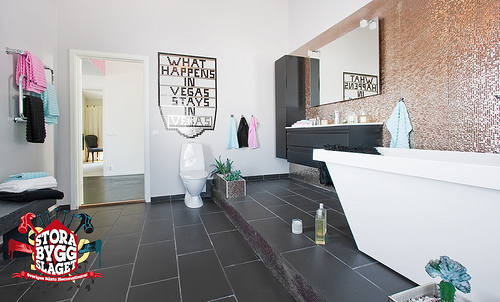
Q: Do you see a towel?
A: Yes, there is a towel.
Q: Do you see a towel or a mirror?
A: Yes, there is a towel.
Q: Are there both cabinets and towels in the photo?
A: Yes, there are both a towel and a cabinet.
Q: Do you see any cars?
A: No, there are no cars.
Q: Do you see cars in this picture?
A: No, there are no cars.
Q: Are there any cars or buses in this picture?
A: No, there are no cars or buses.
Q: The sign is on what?
A: The sign is on the wall.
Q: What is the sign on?
A: The sign is on the wall.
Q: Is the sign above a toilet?
A: Yes, the sign is above a toilet.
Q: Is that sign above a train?
A: No, the sign is above a toilet.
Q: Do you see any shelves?
A: No, there are no shelves.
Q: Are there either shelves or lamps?
A: No, there are no shelves or lamps.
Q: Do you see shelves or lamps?
A: No, there are no shelves or lamps.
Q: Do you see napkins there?
A: No, there are no napkins.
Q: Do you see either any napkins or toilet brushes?
A: No, there are no napkins or toilet brushes.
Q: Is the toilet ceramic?
A: Yes, the toilet is ceramic.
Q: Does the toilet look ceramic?
A: Yes, the toilet is ceramic.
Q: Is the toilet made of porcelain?
A: Yes, the toilet is made of porcelain.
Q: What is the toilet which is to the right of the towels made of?
A: The toilet is made of porcelain.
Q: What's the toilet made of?
A: The toilet is made of porcelain.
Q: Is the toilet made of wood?
A: No, the toilet is made of porcelain.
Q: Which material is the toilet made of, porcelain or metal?
A: The toilet is made of porcelain.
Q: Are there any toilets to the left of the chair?
A: No, the toilet is to the right of the chair.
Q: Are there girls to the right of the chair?
A: No, there is a toilet to the right of the chair.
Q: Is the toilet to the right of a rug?
A: No, the toilet is to the right of the chair.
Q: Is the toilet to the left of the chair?
A: No, the toilet is to the right of the chair.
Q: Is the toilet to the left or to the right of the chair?
A: The toilet is to the right of the chair.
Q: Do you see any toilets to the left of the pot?
A: Yes, there is a toilet to the left of the pot.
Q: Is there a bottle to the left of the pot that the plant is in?
A: No, there is a toilet to the left of the pot.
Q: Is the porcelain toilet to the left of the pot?
A: Yes, the toilet is to the left of the pot.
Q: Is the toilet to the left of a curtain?
A: No, the toilet is to the left of the pot.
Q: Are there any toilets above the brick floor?
A: Yes, there is a toilet above the floor.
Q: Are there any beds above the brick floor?
A: No, there is a toilet above the floor.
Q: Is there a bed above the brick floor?
A: No, there is a toilet above the floor.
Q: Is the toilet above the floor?
A: Yes, the toilet is above the floor.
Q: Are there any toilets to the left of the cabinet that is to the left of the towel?
A: Yes, there is a toilet to the left of the cabinet.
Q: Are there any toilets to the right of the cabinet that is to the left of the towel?
A: No, the toilet is to the left of the cabinet.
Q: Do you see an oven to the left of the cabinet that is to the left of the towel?
A: No, there is a toilet to the left of the cabinet.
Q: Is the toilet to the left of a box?
A: No, the toilet is to the left of a cabinet.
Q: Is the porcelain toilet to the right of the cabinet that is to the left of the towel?
A: No, the toilet is to the left of the cabinet.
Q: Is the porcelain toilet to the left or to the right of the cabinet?
A: The toilet is to the left of the cabinet.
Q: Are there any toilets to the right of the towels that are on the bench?
A: Yes, there is a toilet to the right of the towels.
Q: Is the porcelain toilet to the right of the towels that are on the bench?
A: Yes, the toilet is to the right of the towels.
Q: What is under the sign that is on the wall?
A: The toilet is under the sign.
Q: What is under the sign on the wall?
A: The toilet is under the sign.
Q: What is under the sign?
A: The toilet is under the sign.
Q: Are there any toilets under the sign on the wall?
A: Yes, there is a toilet under the sign.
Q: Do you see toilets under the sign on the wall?
A: Yes, there is a toilet under the sign.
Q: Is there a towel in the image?
A: Yes, there is a towel.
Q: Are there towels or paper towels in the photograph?
A: Yes, there is a towel.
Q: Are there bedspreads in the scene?
A: No, there are no bedspreads.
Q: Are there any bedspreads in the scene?
A: No, there are no bedspreads.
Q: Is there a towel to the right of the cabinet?
A: Yes, there is a towel to the right of the cabinet.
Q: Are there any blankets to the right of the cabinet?
A: No, there is a towel to the right of the cabinet.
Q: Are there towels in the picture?
A: Yes, there is a towel.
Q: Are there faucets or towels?
A: Yes, there is a towel.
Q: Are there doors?
A: Yes, there is a door.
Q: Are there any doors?
A: Yes, there is a door.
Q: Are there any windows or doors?
A: Yes, there is a door.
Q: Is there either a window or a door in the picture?
A: Yes, there is a door.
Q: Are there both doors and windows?
A: No, there is a door but no windows.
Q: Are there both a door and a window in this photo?
A: No, there is a door but no windows.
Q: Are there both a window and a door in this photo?
A: No, there is a door but no windows.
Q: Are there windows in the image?
A: No, there are no windows.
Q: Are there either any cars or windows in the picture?
A: No, there are no windows or cars.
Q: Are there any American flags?
A: No, there are no American flags.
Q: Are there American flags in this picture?
A: No, there are no American flags.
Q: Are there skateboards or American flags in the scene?
A: No, there are no American flags or skateboards.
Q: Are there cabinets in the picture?
A: Yes, there is a cabinet.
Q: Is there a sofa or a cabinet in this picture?
A: Yes, there is a cabinet.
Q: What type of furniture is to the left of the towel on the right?
A: The piece of furniture is a cabinet.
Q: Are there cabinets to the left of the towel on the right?
A: Yes, there is a cabinet to the left of the towel.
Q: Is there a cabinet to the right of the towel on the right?
A: No, the cabinet is to the left of the towel.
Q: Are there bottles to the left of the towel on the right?
A: No, there is a cabinet to the left of the towel.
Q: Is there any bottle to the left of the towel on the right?
A: No, there is a cabinet to the left of the towel.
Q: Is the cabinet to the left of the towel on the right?
A: Yes, the cabinet is to the left of the towel.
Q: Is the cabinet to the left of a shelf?
A: No, the cabinet is to the left of the towel.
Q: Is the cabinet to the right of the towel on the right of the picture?
A: No, the cabinet is to the left of the towel.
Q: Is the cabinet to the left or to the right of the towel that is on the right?
A: The cabinet is to the left of the towel.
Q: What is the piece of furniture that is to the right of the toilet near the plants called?
A: The piece of furniture is a cabinet.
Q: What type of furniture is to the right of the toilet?
A: The piece of furniture is a cabinet.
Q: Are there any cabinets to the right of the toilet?
A: Yes, there is a cabinet to the right of the toilet.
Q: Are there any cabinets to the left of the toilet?
A: No, the cabinet is to the right of the toilet.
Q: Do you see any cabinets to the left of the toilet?
A: No, the cabinet is to the right of the toilet.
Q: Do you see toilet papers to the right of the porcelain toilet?
A: No, there is a cabinet to the right of the toilet.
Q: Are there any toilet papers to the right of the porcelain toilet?
A: No, there is a cabinet to the right of the toilet.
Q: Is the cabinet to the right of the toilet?
A: Yes, the cabinet is to the right of the toilet.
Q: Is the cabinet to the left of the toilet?
A: No, the cabinet is to the right of the toilet.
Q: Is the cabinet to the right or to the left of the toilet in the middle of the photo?
A: The cabinet is to the right of the toilet.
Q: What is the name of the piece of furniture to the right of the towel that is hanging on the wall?
A: The piece of furniture is a cabinet.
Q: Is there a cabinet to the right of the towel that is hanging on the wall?
A: Yes, there is a cabinet to the right of the towel.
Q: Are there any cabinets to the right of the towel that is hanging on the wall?
A: Yes, there is a cabinet to the right of the towel.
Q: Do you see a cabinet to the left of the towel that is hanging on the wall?
A: No, the cabinet is to the right of the towel.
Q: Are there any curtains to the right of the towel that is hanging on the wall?
A: No, there is a cabinet to the right of the towel.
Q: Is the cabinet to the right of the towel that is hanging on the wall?
A: Yes, the cabinet is to the right of the towel.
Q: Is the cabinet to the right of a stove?
A: No, the cabinet is to the right of the towel.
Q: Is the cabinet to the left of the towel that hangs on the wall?
A: No, the cabinet is to the right of the towel.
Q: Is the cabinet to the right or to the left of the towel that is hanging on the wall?
A: The cabinet is to the right of the towel.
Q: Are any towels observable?
A: Yes, there is a towel.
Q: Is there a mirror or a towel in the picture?
A: Yes, there is a towel.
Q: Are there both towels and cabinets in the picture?
A: Yes, there are both a towel and a cabinet.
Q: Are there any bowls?
A: No, there are no bowls.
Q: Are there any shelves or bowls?
A: No, there are no bowls or shelves.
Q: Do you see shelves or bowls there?
A: No, there are no bowls or shelves.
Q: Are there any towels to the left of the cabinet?
A: Yes, there is a towel to the left of the cabinet.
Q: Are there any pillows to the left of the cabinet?
A: No, there is a towel to the left of the cabinet.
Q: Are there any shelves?
A: No, there are no shelves.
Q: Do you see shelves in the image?
A: No, there are no shelves.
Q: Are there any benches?
A: Yes, there is a bench.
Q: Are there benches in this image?
A: Yes, there is a bench.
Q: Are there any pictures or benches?
A: Yes, there is a bench.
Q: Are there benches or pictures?
A: Yes, there is a bench.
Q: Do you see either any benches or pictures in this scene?
A: Yes, there is a bench.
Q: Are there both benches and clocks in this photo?
A: No, there is a bench but no clocks.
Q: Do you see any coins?
A: No, there are no coins.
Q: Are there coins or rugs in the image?
A: No, there are no coins or rugs.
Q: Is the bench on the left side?
A: Yes, the bench is on the left of the image.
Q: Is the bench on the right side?
A: No, the bench is on the left of the image.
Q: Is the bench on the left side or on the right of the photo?
A: The bench is on the left of the image.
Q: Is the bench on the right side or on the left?
A: The bench is on the left of the image.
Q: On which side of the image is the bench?
A: The bench is on the left of the image.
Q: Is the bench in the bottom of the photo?
A: Yes, the bench is in the bottom of the image.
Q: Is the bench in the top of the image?
A: No, the bench is in the bottom of the image.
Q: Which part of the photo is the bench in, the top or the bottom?
A: The bench is in the bottom of the image.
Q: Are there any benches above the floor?
A: Yes, there is a bench above the floor.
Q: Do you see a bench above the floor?
A: Yes, there is a bench above the floor.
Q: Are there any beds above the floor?
A: No, there is a bench above the floor.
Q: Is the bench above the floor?
A: Yes, the bench is above the floor.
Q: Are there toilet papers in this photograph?
A: No, there are no toilet papers.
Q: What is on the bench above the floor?
A: The towels are on the bench.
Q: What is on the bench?
A: The towels are on the bench.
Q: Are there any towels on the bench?
A: Yes, there are towels on the bench.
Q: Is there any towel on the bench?
A: Yes, there are towels on the bench.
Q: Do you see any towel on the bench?
A: Yes, there are towels on the bench.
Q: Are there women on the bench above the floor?
A: No, there are towels on the bench.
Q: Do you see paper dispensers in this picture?
A: No, there are no paper dispensers.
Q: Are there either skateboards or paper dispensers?
A: No, there are no paper dispensers or skateboards.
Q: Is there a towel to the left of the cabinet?
A: Yes, there are towels to the left of the cabinet.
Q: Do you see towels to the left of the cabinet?
A: Yes, there are towels to the left of the cabinet.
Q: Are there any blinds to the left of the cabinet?
A: No, there are towels to the left of the cabinet.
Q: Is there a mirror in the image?
A: Yes, there is a mirror.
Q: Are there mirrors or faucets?
A: Yes, there is a mirror.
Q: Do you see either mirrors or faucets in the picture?
A: Yes, there is a mirror.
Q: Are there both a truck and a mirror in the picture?
A: No, there is a mirror but no trucks.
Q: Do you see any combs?
A: No, there are no combs.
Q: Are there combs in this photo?
A: No, there are no combs.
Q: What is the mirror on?
A: The mirror is on the wall.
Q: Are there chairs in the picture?
A: Yes, there is a chair.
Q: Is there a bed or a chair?
A: Yes, there is a chair.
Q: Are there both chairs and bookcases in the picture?
A: No, there is a chair but no bookcases.